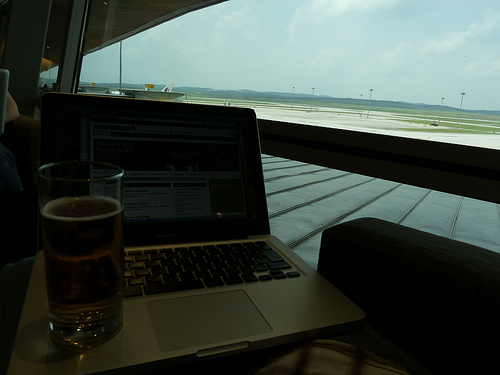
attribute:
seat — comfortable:
[253, 327, 428, 372]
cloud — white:
[384, 8, 480, 65]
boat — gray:
[113, 78, 188, 103]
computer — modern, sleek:
[14, 79, 376, 374]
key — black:
[190, 260, 223, 280]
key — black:
[233, 252, 259, 266]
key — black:
[238, 242, 268, 262]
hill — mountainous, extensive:
[79, 79, 219, 95]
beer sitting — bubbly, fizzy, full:
[9, 136, 164, 312]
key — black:
[134, 263, 146, 273]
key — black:
[169, 253, 177, 269]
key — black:
[199, 255, 212, 266]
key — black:
[232, 250, 244, 258]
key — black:
[201, 275, 212, 288]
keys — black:
[168, 256, 243, 279]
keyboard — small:
[50, 236, 302, 301]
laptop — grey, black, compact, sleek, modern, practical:
[8, 86, 375, 373]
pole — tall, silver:
[455, 81, 472, 122]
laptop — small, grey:
[38, 82, 372, 373]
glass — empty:
[28, 139, 165, 359]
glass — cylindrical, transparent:
[36, 154, 128, 352]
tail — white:
[164, 83, 174, 97]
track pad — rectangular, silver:
[145, 286, 277, 354]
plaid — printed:
[255, 317, 409, 364]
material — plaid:
[308, 313, 406, 351]